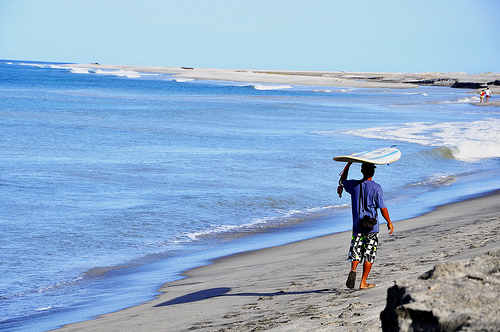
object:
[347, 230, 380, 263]
shorts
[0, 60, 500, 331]
water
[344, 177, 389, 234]
shirt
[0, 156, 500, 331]
tide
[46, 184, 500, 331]
beach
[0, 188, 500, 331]
shore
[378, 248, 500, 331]
rock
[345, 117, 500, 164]
foam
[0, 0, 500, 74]
sky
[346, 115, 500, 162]
wave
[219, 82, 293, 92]
wave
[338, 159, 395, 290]
he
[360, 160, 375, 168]
cap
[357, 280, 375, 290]
flip flops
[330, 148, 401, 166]
surfboard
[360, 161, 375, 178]
head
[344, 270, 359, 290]
sole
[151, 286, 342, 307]
shadow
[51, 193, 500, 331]
sand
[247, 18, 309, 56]
blue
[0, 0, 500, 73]
clouds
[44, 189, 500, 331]
ground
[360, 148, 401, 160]
stripes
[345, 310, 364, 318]
flop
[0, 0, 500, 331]
out